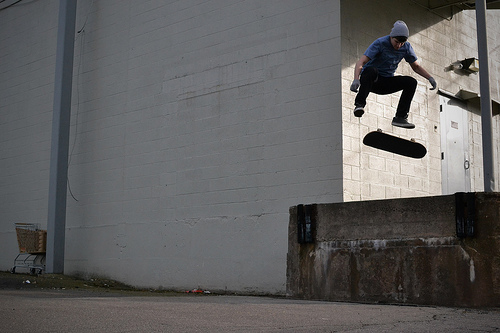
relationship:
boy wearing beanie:
[349, 20, 436, 129] [388, 20, 411, 42]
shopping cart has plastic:
[10, 222, 47, 274] [29, 238, 35, 250]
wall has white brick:
[3, 0, 498, 305] [3, 2, 498, 314]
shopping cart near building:
[8, 220, 45, 277] [21, 6, 343, 320]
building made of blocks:
[4, 0, 500, 310] [188, 82, 347, 192]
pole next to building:
[45, 6, 75, 278] [27, 3, 344, 296]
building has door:
[4, 0, 498, 310] [438, 92, 474, 193]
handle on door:
[463, 158, 473, 170] [438, 92, 474, 193]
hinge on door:
[432, 100, 452, 117] [421, 72, 483, 199]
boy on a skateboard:
[349, 20, 436, 129] [362, 127, 425, 158]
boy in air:
[349, 20, 436, 129] [219, 159, 411, 258]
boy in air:
[343, 20, 437, 138] [240, 134, 406, 241]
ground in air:
[384, 183, 445, 243] [240, 159, 363, 221]